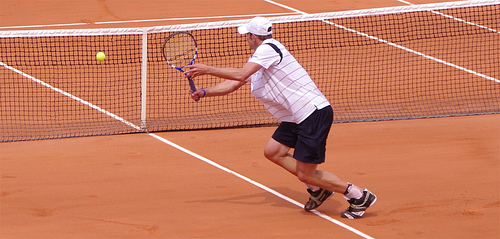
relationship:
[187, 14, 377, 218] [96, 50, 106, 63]
man about to hit a tennis ball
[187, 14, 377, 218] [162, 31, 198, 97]
man swinging a tennis racket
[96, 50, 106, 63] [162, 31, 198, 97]
tennis ball in mid air toward tennis racket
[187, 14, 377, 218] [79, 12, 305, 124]
man playing tennis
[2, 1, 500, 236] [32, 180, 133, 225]
tennis court surface made of clay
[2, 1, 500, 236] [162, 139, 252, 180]
tennis court has painted lines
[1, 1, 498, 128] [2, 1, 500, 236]
tennis net across tennis court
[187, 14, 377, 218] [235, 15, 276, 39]
man wearing a white hat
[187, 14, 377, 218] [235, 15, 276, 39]
man wearing a baseball white hat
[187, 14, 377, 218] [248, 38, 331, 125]
man wearing a striped shirt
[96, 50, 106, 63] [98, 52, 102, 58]
tennis ball flying in air yellow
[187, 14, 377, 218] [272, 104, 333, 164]
man wearing navy blue shorts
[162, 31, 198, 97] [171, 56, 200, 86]
tennis racket colored black and blue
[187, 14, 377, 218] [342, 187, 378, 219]
man wearing white blue tennis shoes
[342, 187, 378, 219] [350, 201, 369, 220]
tennis shoes worn are white and blue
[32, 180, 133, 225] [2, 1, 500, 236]
clay red on tennis court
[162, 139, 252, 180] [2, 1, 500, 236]
painted lines are boundary lines o tennis court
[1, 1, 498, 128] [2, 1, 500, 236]
tennis net in middle of tennis court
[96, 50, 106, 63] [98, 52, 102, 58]
tennis ball in mid air yellow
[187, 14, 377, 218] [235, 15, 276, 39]
tennis player wearing a white hat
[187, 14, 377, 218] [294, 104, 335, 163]
man wearing black shorts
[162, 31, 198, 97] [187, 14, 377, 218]
tennis racket held in hands of man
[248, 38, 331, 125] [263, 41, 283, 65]
striped shirt has dark stripes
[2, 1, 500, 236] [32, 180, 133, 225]
tennis court has orange clay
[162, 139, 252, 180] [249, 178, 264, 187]
painted lines on tennis court are white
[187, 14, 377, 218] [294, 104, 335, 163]
man wearing polynylon black shorts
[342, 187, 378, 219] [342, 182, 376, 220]
tennis shoes on mans left foot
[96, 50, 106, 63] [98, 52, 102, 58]
tennis ball neon yellow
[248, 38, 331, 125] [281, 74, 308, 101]
striped shirt worn has thin black stripes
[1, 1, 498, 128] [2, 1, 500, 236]
tennis net long and low on tennis court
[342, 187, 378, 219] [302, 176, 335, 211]
tennis shoes on mans right foot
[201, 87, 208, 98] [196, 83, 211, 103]
blue bracelet on mans right wrist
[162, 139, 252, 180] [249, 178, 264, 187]
painted lines or boundries are white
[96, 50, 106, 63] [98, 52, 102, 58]
tennis ball used yellow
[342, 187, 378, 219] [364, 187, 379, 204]
tennis shoes worn by man are black and white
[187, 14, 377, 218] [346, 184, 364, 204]
man wearing socks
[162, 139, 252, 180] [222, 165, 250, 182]
painted lines in middle of court are white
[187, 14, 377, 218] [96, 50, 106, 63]
man going for tennis ball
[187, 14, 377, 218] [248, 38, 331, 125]
man wear a striped shirt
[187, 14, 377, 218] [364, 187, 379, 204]
man stripped shirt black and white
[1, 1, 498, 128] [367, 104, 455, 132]
tennis net or gate on ground